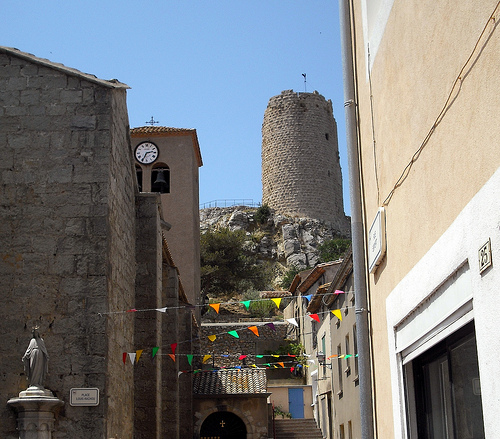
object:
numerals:
[145, 144, 148, 147]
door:
[200, 411, 247, 438]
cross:
[220, 420, 226, 428]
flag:
[126, 309, 137, 313]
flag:
[156, 307, 168, 313]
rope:
[99, 290, 355, 369]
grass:
[200, 201, 351, 317]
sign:
[69, 388, 100, 407]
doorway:
[200, 410, 248, 438]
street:
[269, 416, 335, 439]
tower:
[129, 125, 203, 328]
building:
[267, 377, 313, 419]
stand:
[6, 388, 56, 439]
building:
[342, 0, 498, 439]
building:
[0, 47, 202, 439]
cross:
[145, 116, 159, 126]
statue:
[21, 324, 49, 391]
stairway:
[272, 418, 323, 439]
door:
[288, 388, 305, 419]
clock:
[134, 141, 160, 166]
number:
[478, 241, 492, 275]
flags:
[302, 72, 307, 92]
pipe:
[344, 106, 373, 439]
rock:
[200, 207, 325, 265]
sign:
[368, 207, 386, 274]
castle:
[260, 89, 347, 231]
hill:
[227, 288, 278, 317]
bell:
[150, 167, 170, 194]